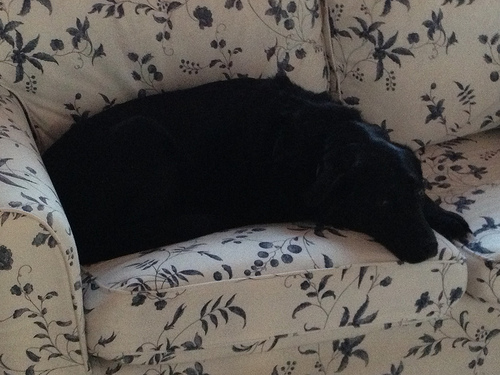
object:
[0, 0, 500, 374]
couch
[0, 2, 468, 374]
seat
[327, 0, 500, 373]
seat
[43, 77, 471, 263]
dog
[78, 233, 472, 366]
cushion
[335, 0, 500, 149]
cushion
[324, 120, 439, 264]
head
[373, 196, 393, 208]
eyes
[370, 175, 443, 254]
face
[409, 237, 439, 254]
snout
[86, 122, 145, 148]
fur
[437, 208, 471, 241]
paw